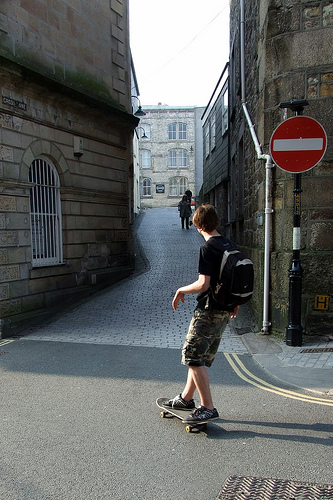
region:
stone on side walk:
[263, 345, 311, 365]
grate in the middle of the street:
[211, 466, 291, 491]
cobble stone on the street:
[101, 310, 153, 334]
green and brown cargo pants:
[189, 333, 219, 360]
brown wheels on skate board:
[153, 404, 166, 418]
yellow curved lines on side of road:
[228, 348, 290, 392]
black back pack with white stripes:
[213, 243, 264, 313]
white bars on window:
[12, 156, 72, 269]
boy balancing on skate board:
[162, 198, 234, 413]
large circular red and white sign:
[258, 114, 331, 174]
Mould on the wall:
[79, 79, 92, 86]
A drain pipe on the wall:
[240, 43, 244, 92]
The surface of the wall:
[37, 11, 85, 37]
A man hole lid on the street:
[248, 485, 293, 498]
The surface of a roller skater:
[179, 411, 187, 414]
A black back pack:
[228, 260, 247, 296]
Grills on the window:
[37, 202, 53, 239]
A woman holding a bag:
[189, 221, 191, 224]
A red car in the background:
[191, 199, 194, 203]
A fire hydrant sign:
[315, 295, 326, 308]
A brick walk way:
[87, 312, 127, 325]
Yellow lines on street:
[241, 364, 271, 397]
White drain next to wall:
[256, 291, 273, 343]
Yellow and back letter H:
[306, 290, 330, 314]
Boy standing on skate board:
[152, 384, 230, 441]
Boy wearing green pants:
[170, 295, 243, 383]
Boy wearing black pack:
[200, 234, 266, 321]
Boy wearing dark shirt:
[179, 233, 254, 316]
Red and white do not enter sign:
[256, 105, 331, 179]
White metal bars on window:
[20, 147, 72, 275]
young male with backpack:
[155, 205, 258, 432]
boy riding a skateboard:
[150, 201, 258, 432]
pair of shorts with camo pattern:
[180, 303, 234, 372]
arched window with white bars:
[12, 139, 70, 275]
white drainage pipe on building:
[231, 25, 282, 335]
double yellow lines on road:
[223, 348, 331, 407]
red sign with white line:
[269, 112, 329, 176]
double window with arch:
[165, 116, 189, 143]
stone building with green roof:
[139, 98, 197, 208]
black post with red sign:
[269, 95, 321, 351]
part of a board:
[180, 405, 186, 412]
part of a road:
[75, 317, 92, 380]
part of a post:
[290, 317, 292, 325]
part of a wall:
[286, 308, 298, 322]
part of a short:
[189, 341, 197, 353]